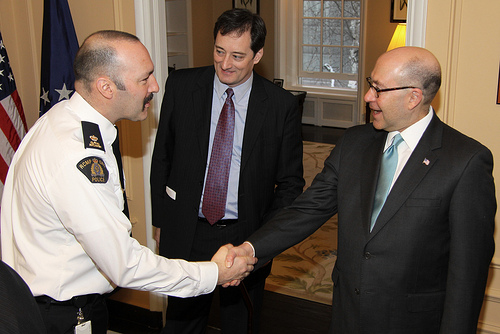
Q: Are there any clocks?
A: No, there are no clocks.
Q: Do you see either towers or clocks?
A: No, there are no clocks or towers.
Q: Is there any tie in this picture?
A: Yes, there is a tie.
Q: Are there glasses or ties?
A: Yes, there is a tie.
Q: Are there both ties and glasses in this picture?
A: Yes, there are both a tie and glasses.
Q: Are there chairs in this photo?
A: No, there are no chairs.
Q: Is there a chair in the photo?
A: No, there are no chairs.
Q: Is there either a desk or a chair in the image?
A: No, there are no chairs or desks.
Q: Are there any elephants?
A: Yes, there is an elephant.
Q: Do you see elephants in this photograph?
A: Yes, there is an elephant.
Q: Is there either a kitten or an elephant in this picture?
A: Yes, there is an elephant.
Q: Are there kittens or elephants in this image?
A: Yes, there is an elephant.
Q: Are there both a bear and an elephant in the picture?
A: No, there is an elephant but no bears.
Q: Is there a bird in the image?
A: No, there are no birds.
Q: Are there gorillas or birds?
A: No, there are no birds or gorillas.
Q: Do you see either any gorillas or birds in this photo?
A: No, there are no birds or gorillas.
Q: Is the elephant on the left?
A: Yes, the elephant is on the left of the image.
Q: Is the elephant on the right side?
A: No, the elephant is on the left of the image.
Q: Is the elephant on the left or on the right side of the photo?
A: The elephant is on the left of the image.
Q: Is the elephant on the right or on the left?
A: The elephant is on the left of the image.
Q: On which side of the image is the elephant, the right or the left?
A: The elephant is on the left of the image.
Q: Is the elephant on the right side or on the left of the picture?
A: The elephant is on the left of the image.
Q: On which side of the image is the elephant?
A: The elephant is on the left of the image.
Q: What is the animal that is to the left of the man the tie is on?
A: The animal is an elephant.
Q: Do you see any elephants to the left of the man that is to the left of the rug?
A: Yes, there is an elephant to the left of the man.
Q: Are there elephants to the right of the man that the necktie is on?
A: No, the elephant is to the left of the man.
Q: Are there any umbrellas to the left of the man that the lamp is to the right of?
A: No, there is an elephant to the left of the man.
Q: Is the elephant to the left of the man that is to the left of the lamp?
A: Yes, the elephant is to the left of the man.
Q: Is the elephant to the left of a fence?
A: No, the elephant is to the left of the man.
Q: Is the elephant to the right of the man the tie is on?
A: No, the elephant is to the left of the man.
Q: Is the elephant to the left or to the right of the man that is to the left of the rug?
A: The elephant is to the left of the man.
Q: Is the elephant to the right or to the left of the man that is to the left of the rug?
A: The elephant is to the left of the man.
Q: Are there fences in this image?
A: No, there are no fences.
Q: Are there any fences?
A: No, there are no fences.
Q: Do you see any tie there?
A: Yes, there is a tie.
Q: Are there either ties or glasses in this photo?
A: Yes, there is a tie.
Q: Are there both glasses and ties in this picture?
A: Yes, there are both a tie and glasses.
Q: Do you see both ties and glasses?
A: Yes, there are both a tie and glasses.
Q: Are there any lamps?
A: Yes, there is a lamp.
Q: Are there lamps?
A: Yes, there is a lamp.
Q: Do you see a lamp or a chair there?
A: Yes, there is a lamp.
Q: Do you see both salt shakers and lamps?
A: No, there is a lamp but no salt shakers.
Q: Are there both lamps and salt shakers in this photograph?
A: No, there is a lamp but no salt shakers.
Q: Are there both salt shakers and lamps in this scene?
A: No, there is a lamp but no salt shakers.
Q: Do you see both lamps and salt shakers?
A: No, there is a lamp but no salt shakers.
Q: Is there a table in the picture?
A: No, there are no tables.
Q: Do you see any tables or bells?
A: No, there are no tables or bells.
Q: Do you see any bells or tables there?
A: No, there are no tables or bells.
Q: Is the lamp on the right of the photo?
A: Yes, the lamp is on the right of the image.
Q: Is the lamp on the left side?
A: No, the lamp is on the right of the image.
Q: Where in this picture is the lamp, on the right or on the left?
A: The lamp is on the right of the image.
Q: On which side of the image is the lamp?
A: The lamp is on the right of the image.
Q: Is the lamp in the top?
A: Yes, the lamp is in the top of the image.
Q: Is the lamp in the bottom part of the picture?
A: No, the lamp is in the top of the image.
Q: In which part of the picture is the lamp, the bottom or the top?
A: The lamp is in the top of the image.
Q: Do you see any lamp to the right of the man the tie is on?
A: Yes, there is a lamp to the right of the man.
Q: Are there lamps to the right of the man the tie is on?
A: Yes, there is a lamp to the right of the man.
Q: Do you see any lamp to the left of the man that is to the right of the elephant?
A: No, the lamp is to the right of the man.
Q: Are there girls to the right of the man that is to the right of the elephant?
A: No, there is a lamp to the right of the man.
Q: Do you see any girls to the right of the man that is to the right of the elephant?
A: No, there is a lamp to the right of the man.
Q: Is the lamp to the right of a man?
A: Yes, the lamp is to the right of a man.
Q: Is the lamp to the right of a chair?
A: No, the lamp is to the right of a man.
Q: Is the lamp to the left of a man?
A: No, the lamp is to the right of a man.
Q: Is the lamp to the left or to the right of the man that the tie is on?
A: The lamp is to the right of the man.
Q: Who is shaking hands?
A: The man is shaking hands.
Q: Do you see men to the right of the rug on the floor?
A: Yes, there is a man to the right of the rug.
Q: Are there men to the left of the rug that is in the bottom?
A: No, the man is to the right of the rug.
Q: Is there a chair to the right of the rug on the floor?
A: No, there is a man to the right of the rug.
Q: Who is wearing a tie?
A: The man is wearing a tie.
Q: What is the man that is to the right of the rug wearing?
A: The man is wearing a necktie.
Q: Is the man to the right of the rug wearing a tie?
A: Yes, the man is wearing a tie.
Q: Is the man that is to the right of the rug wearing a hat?
A: No, the man is wearing a tie.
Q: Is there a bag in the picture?
A: No, there are no bags.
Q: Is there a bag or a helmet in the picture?
A: No, there are no bags or helmets.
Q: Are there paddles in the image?
A: No, there are no paddles.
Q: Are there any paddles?
A: No, there are no paddles.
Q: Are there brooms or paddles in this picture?
A: No, there are no paddles or brooms.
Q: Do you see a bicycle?
A: No, there are no bicycles.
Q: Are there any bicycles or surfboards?
A: No, there are no bicycles or surfboards.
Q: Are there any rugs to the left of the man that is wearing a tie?
A: Yes, there is a rug to the left of the man.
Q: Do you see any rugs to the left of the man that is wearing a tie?
A: Yes, there is a rug to the left of the man.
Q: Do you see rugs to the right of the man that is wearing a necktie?
A: No, the rug is to the left of the man.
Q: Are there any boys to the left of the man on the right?
A: No, there is a rug to the left of the man.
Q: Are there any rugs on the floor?
A: Yes, there is a rug on the floor.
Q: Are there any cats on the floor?
A: No, there is a rug on the floor.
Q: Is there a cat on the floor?
A: No, there is a rug on the floor.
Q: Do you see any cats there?
A: No, there are no cats.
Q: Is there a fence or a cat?
A: No, there are no cats or fences.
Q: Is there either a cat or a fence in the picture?
A: No, there are no cats or fences.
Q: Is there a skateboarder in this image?
A: No, there are no skateboarders.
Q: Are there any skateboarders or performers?
A: No, there are no skateboarders or performers.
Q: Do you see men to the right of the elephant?
A: Yes, there is a man to the right of the elephant.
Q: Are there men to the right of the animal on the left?
A: Yes, there is a man to the right of the elephant.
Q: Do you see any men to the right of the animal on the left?
A: Yes, there is a man to the right of the elephant.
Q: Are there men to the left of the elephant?
A: No, the man is to the right of the elephant.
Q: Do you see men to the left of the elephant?
A: No, the man is to the right of the elephant.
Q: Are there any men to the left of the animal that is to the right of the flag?
A: No, the man is to the right of the elephant.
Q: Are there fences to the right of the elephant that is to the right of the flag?
A: No, there is a man to the right of the elephant.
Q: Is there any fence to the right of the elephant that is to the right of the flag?
A: No, there is a man to the right of the elephant.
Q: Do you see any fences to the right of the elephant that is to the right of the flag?
A: No, there is a man to the right of the elephant.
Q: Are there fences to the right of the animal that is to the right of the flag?
A: No, there is a man to the right of the elephant.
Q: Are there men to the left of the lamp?
A: Yes, there is a man to the left of the lamp.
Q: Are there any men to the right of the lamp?
A: No, the man is to the left of the lamp.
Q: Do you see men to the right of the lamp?
A: No, the man is to the left of the lamp.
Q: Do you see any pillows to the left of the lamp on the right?
A: No, there is a man to the left of the lamp.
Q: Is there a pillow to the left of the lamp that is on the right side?
A: No, there is a man to the left of the lamp.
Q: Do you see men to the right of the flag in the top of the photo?
A: Yes, there is a man to the right of the flag.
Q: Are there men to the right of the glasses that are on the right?
A: No, the man is to the left of the glasses.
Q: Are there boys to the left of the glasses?
A: No, there is a man to the left of the glasses.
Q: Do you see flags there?
A: Yes, there is a flag.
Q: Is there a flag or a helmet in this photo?
A: Yes, there is a flag.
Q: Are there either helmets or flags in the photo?
A: Yes, there is a flag.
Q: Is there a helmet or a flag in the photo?
A: Yes, there is a flag.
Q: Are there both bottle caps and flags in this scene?
A: No, there is a flag but no bottle caps.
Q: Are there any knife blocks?
A: No, there are no knife blocks.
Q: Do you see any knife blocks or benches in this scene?
A: No, there are no knife blocks or benches.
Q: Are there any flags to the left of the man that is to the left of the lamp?
A: Yes, there is a flag to the left of the man.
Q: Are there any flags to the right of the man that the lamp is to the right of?
A: No, the flag is to the left of the man.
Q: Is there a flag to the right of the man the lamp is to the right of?
A: No, the flag is to the left of the man.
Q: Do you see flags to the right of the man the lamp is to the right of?
A: No, the flag is to the left of the man.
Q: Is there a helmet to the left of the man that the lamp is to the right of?
A: No, there is a flag to the left of the man.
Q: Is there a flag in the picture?
A: Yes, there is a flag.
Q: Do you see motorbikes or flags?
A: Yes, there is a flag.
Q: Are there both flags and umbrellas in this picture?
A: No, there is a flag but no umbrellas.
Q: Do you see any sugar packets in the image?
A: No, there are no sugar packets.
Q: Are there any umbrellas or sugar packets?
A: No, there are no sugar packets or umbrellas.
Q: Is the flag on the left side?
A: Yes, the flag is on the left of the image.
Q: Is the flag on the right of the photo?
A: No, the flag is on the left of the image.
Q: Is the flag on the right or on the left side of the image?
A: The flag is on the left of the image.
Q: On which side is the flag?
A: The flag is on the left of the image.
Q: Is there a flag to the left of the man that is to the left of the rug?
A: Yes, there is a flag to the left of the man.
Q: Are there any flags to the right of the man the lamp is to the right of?
A: No, the flag is to the left of the man.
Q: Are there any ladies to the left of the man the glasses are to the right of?
A: No, there is a flag to the left of the man.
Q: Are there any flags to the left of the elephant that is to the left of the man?
A: Yes, there is a flag to the left of the elephant.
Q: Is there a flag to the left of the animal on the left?
A: Yes, there is a flag to the left of the elephant.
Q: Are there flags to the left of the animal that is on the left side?
A: Yes, there is a flag to the left of the elephant.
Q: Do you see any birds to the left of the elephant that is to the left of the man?
A: No, there is a flag to the left of the elephant.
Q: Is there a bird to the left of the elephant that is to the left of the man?
A: No, there is a flag to the left of the elephant.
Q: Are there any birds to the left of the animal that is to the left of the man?
A: No, there is a flag to the left of the elephant.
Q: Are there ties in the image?
A: Yes, there is a tie.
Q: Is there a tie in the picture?
A: Yes, there is a tie.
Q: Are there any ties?
A: Yes, there is a tie.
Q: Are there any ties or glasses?
A: Yes, there is a tie.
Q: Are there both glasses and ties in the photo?
A: Yes, there are both a tie and glasses.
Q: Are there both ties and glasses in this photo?
A: Yes, there are both a tie and glasses.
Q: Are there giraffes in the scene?
A: No, there are no giraffes.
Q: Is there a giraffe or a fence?
A: No, there are no giraffes or fences.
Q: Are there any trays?
A: No, there are no trays.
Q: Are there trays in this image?
A: No, there are no trays.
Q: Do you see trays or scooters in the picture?
A: No, there are no trays or scooters.